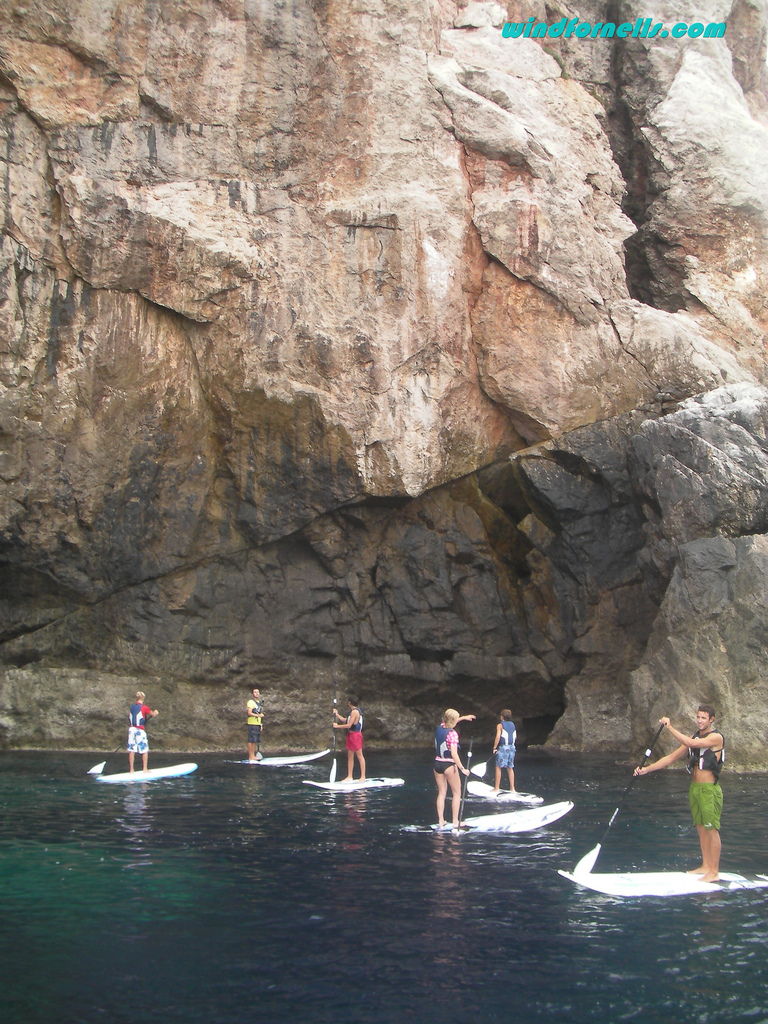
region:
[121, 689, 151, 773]
A person is standing on surfing board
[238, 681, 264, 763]
A person is standing on surfing board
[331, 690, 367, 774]
A person is standing on surfing board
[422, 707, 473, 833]
A person is standing on surfing board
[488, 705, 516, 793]
A person is standing on surfing board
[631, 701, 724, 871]
A person is standing on surfing board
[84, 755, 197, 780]
A white surfing board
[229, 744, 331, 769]
A white surfing board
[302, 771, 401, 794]
A white surfing board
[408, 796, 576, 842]
A white surfing board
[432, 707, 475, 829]
white person is standing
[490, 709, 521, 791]
white person is standing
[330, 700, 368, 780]
white person is standing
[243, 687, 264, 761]
white person is standing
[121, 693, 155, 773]
white person is standing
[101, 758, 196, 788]
surfboard is white and long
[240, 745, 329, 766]
surfboard is white and long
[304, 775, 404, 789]
surfboard is white and long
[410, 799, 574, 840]
surfboard is white and long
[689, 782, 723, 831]
The man on the right is wearing shorts.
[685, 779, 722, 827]
The man on the right is wearing green shorts.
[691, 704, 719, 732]
The man on the right has short hair.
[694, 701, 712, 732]
The man on the right has brown hair.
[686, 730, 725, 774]
The man on the right is wearing a vest.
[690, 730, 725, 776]
The man on the right has on a black and white vest.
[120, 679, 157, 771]
person on the surf board in the water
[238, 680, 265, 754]
person on the surf board in the water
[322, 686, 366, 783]
person on the surf board in the water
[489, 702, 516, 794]
person on the surf board in the water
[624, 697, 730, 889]
person on the surf board in the water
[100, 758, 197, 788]
person on the surf board in the water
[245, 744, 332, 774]
person on the surf board in the water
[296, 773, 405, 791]
person on the surf board in the water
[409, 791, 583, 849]
person on the surf board in the water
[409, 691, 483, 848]
woman with black bikini bottom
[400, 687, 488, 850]
woman with black bikini bottom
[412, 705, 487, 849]
woman with black bikini bottom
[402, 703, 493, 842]
woman with black bikini bottom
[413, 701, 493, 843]
woman with black bikini bottom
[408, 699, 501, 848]
woman with black bikini bottom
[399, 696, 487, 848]
woman with black bikini bottom